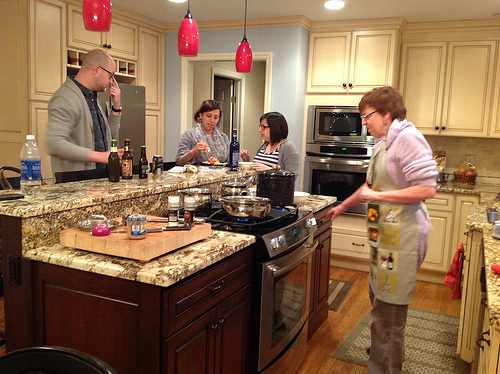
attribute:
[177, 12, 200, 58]
light — red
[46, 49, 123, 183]
man — touching, bald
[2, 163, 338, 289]
counters — marble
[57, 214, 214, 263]
board — thick, wooden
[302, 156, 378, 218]
stove — silver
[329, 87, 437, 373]
woman — talking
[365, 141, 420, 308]
apron — a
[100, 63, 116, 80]
glasses — pair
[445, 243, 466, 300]
towel — red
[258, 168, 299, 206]
pot — steel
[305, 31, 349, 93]
door — wood, beige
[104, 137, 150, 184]
beverage — bottled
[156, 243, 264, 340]
drawer — brown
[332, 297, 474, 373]
rug — green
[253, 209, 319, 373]
oven — steel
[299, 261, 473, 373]
floor — wood